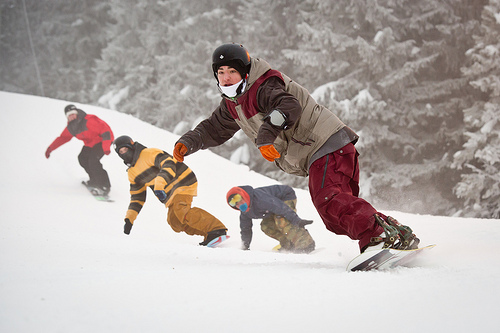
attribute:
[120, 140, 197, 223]
jacket — yellow, black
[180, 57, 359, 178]
coat — red, grey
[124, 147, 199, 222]
sweater — yellow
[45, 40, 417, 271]
people — Four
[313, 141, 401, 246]
pants — maroon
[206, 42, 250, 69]
safety helmet — black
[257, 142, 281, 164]
glove — yellow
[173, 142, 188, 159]
glove — yellow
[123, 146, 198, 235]
yellow jacket — black, stripes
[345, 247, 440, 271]
snowboard — White, black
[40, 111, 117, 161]
snow jacket — red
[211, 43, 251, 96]
cap — black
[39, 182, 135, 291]
snow board — white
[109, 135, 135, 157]
cap — black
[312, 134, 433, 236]
pants — red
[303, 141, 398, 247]
burgundy pants — Burgundy colored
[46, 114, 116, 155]
jacket — red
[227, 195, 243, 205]
goggles — reflective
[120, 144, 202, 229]
coat — black, white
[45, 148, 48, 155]
glove — red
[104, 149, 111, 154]
glove — red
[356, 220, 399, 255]
shoe — black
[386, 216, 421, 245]
shoe — black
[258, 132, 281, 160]
glove — orange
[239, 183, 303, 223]
coat — blue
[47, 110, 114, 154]
coat — red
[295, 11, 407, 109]
snow — white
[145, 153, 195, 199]
stripes — black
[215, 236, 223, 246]
design — red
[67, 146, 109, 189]
pants — black